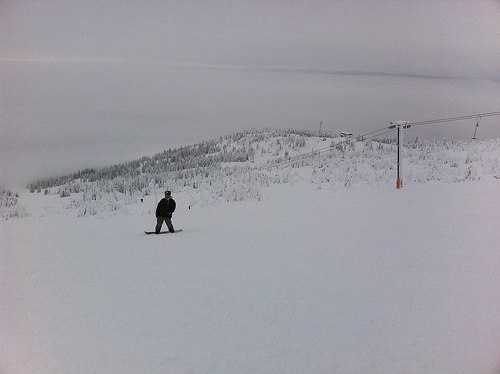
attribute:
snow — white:
[1, 236, 499, 369]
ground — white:
[0, 1, 495, 366]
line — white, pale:
[1, 50, 498, 93]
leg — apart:
[163, 216, 173, 234]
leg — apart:
[156, 215, 163, 232]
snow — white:
[6, 148, 498, 369]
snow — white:
[2, 183, 494, 372]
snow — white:
[0, 127, 498, 372]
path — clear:
[30, 237, 376, 371]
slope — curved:
[7, 178, 497, 301]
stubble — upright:
[280, 143, 363, 177]